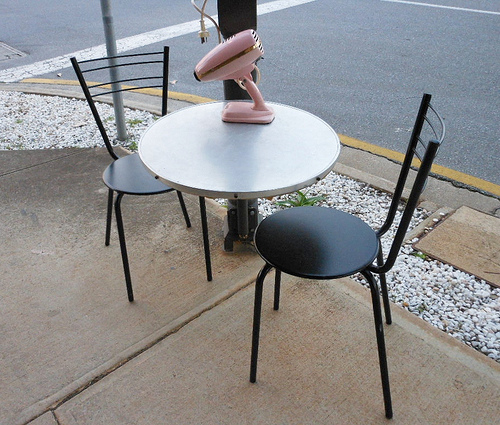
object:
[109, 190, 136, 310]
leg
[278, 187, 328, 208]
weeds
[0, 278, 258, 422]
crack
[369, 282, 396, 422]
leg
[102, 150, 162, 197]
seat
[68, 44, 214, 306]
chair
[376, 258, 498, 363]
gravel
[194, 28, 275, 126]
object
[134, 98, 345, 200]
table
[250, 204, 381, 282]
seat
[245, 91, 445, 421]
chair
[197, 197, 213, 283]
chair leg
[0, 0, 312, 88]
line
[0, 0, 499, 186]
road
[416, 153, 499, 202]
line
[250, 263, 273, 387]
chair leg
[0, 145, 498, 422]
sidewalk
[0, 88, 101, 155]
gravel